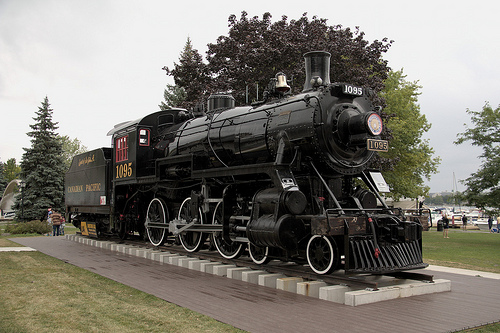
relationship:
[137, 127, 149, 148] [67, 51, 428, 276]
window on car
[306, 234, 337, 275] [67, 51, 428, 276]
wheel for car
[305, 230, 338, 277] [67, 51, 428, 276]
wheel on car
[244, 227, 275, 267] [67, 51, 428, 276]
wheel on car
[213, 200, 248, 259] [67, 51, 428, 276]
wheel on car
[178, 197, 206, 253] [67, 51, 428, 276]
wheel on car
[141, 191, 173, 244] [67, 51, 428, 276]
wheel on car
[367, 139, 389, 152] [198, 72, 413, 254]
license plate for train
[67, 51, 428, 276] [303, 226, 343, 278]
car has wheel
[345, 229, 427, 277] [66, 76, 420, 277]
grill on train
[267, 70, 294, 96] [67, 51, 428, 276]
bell on car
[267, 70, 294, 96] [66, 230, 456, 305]
bell on display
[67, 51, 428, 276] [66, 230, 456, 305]
car on display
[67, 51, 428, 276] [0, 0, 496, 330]
car ion park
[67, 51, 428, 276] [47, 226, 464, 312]
car ion blocks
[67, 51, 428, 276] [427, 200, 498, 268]
car in park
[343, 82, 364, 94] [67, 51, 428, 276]
number in car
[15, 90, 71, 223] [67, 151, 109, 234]
tree behind car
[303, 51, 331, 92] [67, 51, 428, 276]
pipe top of car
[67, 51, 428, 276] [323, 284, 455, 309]
car on bricks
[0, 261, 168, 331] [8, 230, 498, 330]
grass on ground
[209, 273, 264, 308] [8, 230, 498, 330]
water on ground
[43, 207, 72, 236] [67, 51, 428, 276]
people behind car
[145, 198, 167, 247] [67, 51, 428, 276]
wheel of car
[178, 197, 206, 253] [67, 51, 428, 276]
wheel of car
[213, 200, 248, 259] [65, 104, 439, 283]
wheel of train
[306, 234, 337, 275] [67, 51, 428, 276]
wheel of car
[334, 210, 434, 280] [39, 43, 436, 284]
bumper of train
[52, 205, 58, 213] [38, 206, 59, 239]
head of person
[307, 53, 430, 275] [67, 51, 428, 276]
front of car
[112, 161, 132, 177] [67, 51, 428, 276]
number of car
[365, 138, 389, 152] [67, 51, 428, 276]
license plate of car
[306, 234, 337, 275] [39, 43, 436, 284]
wheel of train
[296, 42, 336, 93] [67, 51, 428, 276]
pipe of car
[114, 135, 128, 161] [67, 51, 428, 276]
window of car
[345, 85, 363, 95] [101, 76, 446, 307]
number of train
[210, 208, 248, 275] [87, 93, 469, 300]
wheel of train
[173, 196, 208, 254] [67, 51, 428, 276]
wheel of car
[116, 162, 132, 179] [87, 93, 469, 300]
number on train